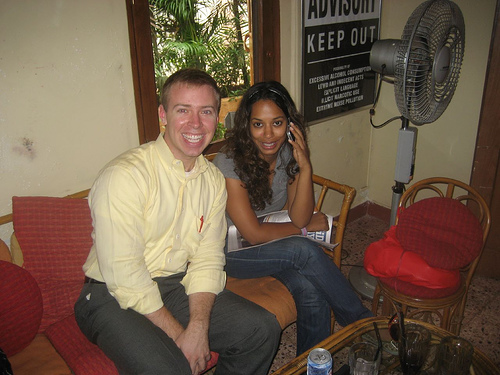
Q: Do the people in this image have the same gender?
A: No, they are both male and female.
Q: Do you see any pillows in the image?
A: Yes, there is a pillow.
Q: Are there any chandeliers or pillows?
A: Yes, there is a pillow.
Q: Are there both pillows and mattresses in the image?
A: No, there is a pillow but no mattresses.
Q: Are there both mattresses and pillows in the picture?
A: No, there is a pillow but no mattresses.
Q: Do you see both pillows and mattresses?
A: No, there is a pillow but no mattresses.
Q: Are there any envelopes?
A: No, there are no envelopes.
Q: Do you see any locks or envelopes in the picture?
A: No, there are no envelopes or locks.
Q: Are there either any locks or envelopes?
A: No, there are no envelopes or locks.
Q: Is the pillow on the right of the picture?
A: Yes, the pillow is on the right of the image.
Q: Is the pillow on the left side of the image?
A: No, the pillow is on the right of the image.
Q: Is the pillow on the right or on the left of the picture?
A: The pillow is on the right of the image.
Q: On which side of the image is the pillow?
A: The pillow is on the right of the image.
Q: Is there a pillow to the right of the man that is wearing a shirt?
A: Yes, there is a pillow to the right of the man.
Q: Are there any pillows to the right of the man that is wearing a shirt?
A: Yes, there is a pillow to the right of the man.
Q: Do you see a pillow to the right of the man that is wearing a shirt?
A: Yes, there is a pillow to the right of the man.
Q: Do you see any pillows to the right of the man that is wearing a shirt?
A: Yes, there is a pillow to the right of the man.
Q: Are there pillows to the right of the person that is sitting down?
A: Yes, there is a pillow to the right of the man.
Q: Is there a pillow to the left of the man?
A: No, the pillow is to the right of the man.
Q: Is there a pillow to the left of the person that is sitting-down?
A: No, the pillow is to the right of the man.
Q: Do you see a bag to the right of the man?
A: No, there is a pillow to the right of the man.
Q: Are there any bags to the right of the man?
A: No, there is a pillow to the right of the man.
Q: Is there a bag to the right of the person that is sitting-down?
A: No, there is a pillow to the right of the man.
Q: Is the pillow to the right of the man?
A: Yes, the pillow is to the right of the man.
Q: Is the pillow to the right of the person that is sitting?
A: Yes, the pillow is to the right of the man.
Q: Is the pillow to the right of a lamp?
A: No, the pillow is to the right of the man.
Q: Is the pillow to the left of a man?
A: No, the pillow is to the right of a man.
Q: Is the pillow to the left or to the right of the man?
A: The pillow is to the right of the man.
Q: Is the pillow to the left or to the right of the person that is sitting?
A: The pillow is to the right of the man.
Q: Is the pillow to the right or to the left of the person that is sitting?
A: The pillow is to the right of the man.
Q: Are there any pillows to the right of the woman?
A: Yes, there is a pillow to the right of the woman.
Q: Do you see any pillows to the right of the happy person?
A: Yes, there is a pillow to the right of the woman.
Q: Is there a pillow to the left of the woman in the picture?
A: No, the pillow is to the right of the woman.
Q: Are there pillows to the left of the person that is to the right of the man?
A: No, the pillow is to the right of the woman.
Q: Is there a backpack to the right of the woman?
A: No, there is a pillow to the right of the woman.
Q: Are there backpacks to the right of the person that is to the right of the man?
A: No, there is a pillow to the right of the woman.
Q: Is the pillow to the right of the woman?
A: Yes, the pillow is to the right of the woman.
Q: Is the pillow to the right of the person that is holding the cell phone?
A: Yes, the pillow is to the right of the woman.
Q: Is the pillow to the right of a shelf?
A: No, the pillow is to the right of the woman.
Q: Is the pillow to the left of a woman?
A: No, the pillow is to the right of a woman.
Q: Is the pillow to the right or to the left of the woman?
A: The pillow is to the right of the woman.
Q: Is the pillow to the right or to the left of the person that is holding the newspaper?
A: The pillow is to the right of the woman.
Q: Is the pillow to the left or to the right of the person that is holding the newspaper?
A: The pillow is to the right of the woman.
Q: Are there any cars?
A: No, there are no cars.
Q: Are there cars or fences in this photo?
A: No, there are no cars or fences.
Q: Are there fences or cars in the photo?
A: No, there are no cars or fences.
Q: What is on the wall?
A: The sign is on the wall.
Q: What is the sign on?
A: The sign is on the wall.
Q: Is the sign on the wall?
A: Yes, the sign is on the wall.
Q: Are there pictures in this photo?
A: No, there are no pictures.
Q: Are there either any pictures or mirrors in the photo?
A: No, there are no pictures or mirrors.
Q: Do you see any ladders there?
A: No, there are no ladders.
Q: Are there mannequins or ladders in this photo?
A: No, there are no ladders or mannequins.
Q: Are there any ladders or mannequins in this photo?
A: No, there are no ladders or mannequins.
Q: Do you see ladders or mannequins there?
A: No, there are no ladders or mannequins.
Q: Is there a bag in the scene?
A: No, there are no bags.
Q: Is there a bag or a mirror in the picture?
A: No, there are no bags or mirrors.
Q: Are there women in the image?
A: Yes, there is a woman.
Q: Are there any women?
A: Yes, there is a woman.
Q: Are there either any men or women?
A: Yes, there is a woman.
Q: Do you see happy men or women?
A: Yes, there is a happy woman.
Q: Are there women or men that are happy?
A: Yes, the woman is happy.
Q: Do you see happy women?
A: Yes, there is a happy woman.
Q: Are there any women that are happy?
A: Yes, there is a woman that is happy.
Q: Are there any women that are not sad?
A: Yes, there is a happy woman.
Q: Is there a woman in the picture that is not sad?
A: Yes, there is a happy woman.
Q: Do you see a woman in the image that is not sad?
A: Yes, there is a happy woman.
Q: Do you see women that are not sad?
A: Yes, there is a happy woman.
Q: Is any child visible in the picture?
A: No, there are no children.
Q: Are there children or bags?
A: No, there are no children or bags.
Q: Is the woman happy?
A: Yes, the woman is happy.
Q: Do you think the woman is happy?
A: Yes, the woman is happy.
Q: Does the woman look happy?
A: Yes, the woman is happy.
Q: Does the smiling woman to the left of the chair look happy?
A: Yes, the woman is happy.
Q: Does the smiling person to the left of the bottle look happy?
A: Yes, the woman is happy.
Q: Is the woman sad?
A: No, the woman is happy.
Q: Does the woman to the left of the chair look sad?
A: No, the woman is happy.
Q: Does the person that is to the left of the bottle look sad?
A: No, the woman is happy.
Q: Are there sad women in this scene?
A: No, there is a woman but she is happy.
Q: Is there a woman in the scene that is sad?
A: No, there is a woman but she is happy.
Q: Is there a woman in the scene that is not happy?
A: No, there is a woman but she is happy.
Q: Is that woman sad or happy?
A: The woman is happy.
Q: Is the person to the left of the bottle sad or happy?
A: The woman is happy.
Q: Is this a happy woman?
A: Yes, this is a happy woman.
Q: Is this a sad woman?
A: No, this is a happy woman.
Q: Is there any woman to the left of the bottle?
A: Yes, there is a woman to the left of the bottle.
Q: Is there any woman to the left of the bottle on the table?
A: Yes, there is a woman to the left of the bottle.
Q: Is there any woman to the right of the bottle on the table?
A: No, the woman is to the left of the bottle.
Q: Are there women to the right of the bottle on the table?
A: No, the woman is to the left of the bottle.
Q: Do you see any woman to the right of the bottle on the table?
A: No, the woman is to the left of the bottle.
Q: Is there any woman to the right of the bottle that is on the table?
A: No, the woman is to the left of the bottle.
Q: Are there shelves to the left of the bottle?
A: No, there is a woman to the left of the bottle.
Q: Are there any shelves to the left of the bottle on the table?
A: No, there is a woman to the left of the bottle.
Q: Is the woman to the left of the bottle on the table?
A: Yes, the woman is to the left of the bottle.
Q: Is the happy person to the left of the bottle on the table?
A: Yes, the woman is to the left of the bottle.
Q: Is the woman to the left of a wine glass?
A: No, the woman is to the left of the bottle.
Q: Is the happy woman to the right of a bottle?
A: No, the woman is to the left of a bottle.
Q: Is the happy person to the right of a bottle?
A: No, the woman is to the left of a bottle.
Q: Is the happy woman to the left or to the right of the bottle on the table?
A: The woman is to the left of the bottle.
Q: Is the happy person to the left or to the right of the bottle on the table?
A: The woman is to the left of the bottle.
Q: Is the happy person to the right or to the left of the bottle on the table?
A: The woman is to the left of the bottle.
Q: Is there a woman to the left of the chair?
A: Yes, there is a woman to the left of the chair.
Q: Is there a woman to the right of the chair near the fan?
A: No, the woman is to the left of the chair.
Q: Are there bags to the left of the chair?
A: No, there is a woman to the left of the chair.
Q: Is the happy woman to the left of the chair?
A: Yes, the woman is to the left of the chair.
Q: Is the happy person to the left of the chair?
A: Yes, the woman is to the left of the chair.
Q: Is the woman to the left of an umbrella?
A: No, the woman is to the left of the chair.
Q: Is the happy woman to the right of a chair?
A: No, the woman is to the left of a chair.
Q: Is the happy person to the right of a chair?
A: No, the woman is to the left of a chair.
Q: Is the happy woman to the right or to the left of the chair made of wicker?
A: The woman is to the left of the chair.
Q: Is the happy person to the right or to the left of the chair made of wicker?
A: The woman is to the left of the chair.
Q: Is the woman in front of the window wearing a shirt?
A: Yes, the woman is wearing a shirt.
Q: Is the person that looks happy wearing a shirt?
A: Yes, the woman is wearing a shirt.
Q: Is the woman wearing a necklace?
A: No, the woman is wearing a shirt.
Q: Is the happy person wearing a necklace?
A: No, the woman is wearing a shirt.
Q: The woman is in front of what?
A: The woman is in front of the window.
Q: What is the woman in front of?
A: The woman is in front of the window.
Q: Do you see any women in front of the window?
A: Yes, there is a woman in front of the window.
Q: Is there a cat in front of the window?
A: No, there is a woman in front of the window.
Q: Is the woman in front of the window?
A: Yes, the woman is in front of the window.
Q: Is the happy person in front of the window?
A: Yes, the woman is in front of the window.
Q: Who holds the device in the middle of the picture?
A: The woman holds the cell phone.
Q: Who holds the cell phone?
A: The woman holds the cell phone.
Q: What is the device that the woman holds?
A: The device is a cell phone.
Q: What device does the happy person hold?
A: The woman holds the cellphone.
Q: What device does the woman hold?
A: The woman holds the cellphone.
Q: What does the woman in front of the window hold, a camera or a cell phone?
A: The woman holds a cell phone.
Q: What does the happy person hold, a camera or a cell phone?
A: The woman holds a cell phone.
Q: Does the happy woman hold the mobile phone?
A: Yes, the woman holds the mobile phone.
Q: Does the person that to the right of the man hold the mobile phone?
A: Yes, the woman holds the mobile phone.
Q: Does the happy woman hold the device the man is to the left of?
A: Yes, the woman holds the mobile phone.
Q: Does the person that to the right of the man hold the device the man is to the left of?
A: Yes, the woman holds the mobile phone.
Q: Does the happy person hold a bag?
A: No, the woman holds the mobile phone.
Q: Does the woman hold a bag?
A: No, the woman holds the mobile phone.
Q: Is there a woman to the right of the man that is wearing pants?
A: Yes, there is a woman to the right of the man.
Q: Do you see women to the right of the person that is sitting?
A: Yes, there is a woman to the right of the man.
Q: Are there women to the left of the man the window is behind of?
A: No, the woman is to the right of the man.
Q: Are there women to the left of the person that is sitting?
A: No, the woman is to the right of the man.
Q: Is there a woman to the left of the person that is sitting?
A: No, the woman is to the right of the man.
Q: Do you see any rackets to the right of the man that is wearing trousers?
A: No, there is a woman to the right of the man.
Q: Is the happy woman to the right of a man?
A: Yes, the woman is to the right of a man.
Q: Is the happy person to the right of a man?
A: Yes, the woman is to the right of a man.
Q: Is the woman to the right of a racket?
A: No, the woman is to the right of a man.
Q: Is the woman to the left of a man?
A: No, the woman is to the right of a man.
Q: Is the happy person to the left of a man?
A: No, the woman is to the right of a man.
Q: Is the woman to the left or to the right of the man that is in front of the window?
A: The woman is to the right of the man.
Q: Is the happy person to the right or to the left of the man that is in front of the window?
A: The woman is to the right of the man.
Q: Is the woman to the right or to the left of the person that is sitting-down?
A: The woman is to the right of the man.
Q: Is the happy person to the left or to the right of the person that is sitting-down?
A: The woman is to the right of the man.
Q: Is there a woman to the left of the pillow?
A: Yes, there is a woman to the left of the pillow.